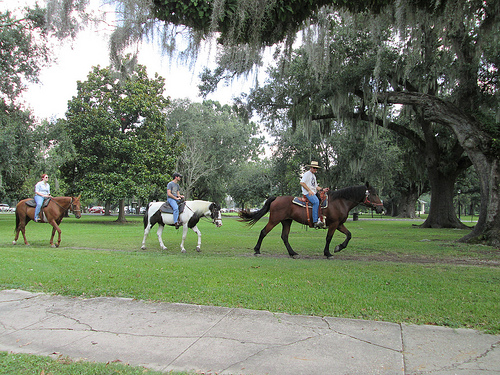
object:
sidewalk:
[0, 287, 499, 374]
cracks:
[42, 326, 244, 343]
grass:
[0, 252, 500, 311]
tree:
[196, 6, 500, 250]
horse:
[15, 194, 78, 246]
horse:
[237, 180, 389, 260]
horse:
[138, 195, 229, 250]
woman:
[32, 172, 53, 223]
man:
[167, 167, 187, 223]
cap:
[172, 168, 186, 178]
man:
[299, 160, 327, 227]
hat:
[308, 160, 323, 169]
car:
[86, 204, 110, 214]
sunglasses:
[313, 167, 319, 169]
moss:
[297, 27, 350, 76]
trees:
[274, 48, 465, 234]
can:
[352, 212, 360, 222]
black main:
[332, 183, 367, 201]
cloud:
[33, 25, 260, 101]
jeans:
[35, 195, 45, 222]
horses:
[140, 197, 227, 251]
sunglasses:
[40, 176, 54, 179]